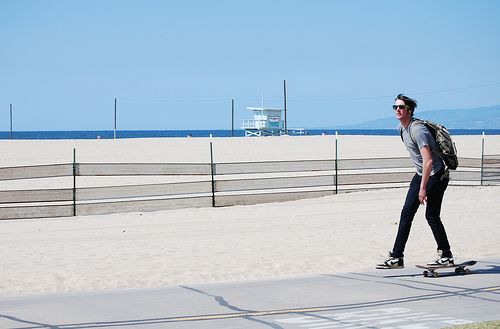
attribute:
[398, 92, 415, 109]
man's hair — black, windblown 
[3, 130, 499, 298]
beach — sand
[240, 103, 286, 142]
lifeguard tower — white, wooden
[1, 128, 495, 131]
sea water — blue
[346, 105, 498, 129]
mountains — distant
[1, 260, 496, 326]
roadway — paved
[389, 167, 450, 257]
jeans — dark-colored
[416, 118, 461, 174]
backpack — man's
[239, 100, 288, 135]
lifeguard stand — white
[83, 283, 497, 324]
divider — yellow